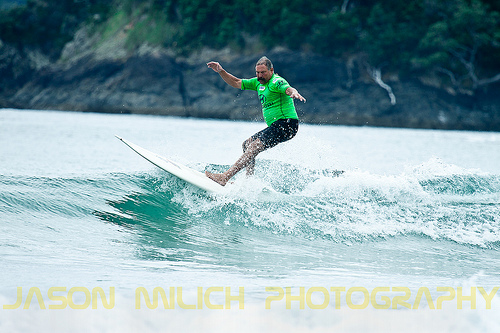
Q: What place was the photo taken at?
A: It was taken at the ocean.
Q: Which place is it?
A: It is an ocean.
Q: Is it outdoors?
A: Yes, it is outdoors.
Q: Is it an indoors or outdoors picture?
A: It is outdoors.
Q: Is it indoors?
A: No, it is outdoors.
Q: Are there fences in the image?
A: No, there are no fences.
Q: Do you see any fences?
A: No, there are no fences.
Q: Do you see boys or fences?
A: No, there are no fences or boys.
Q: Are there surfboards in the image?
A: Yes, there is a surfboard.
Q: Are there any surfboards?
A: Yes, there is a surfboard.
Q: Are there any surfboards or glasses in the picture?
A: Yes, there is a surfboard.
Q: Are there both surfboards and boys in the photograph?
A: No, there is a surfboard but no boys.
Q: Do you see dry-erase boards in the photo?
A: No, there are no dry-erase boards.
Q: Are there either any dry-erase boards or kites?
A: No, there are no dry-erase boards or kites.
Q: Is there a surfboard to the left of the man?
A: Yes, there is a surfboard to the left of the man.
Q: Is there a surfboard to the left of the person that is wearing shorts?
A: Yes, there is a surfboard to the left of the man.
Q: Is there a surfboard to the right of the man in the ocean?
A: No, the surfboard is to the left of the man.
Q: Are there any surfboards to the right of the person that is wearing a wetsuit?
A: No, the surfboard is to the left of the man.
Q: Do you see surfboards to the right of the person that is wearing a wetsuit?
A: No, the surfboard is to the left of the man.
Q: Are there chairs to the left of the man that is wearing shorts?
A: No, there is a surfboard to the left of the man.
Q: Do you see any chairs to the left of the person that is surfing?
A: No, there is a surfboard to the left of the man.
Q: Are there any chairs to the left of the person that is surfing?
A: No, there is a surfboard to the left of the man.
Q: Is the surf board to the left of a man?
A: Yes, the surf board is to the left of a man.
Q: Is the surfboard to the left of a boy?
A: No, the surfboard is to the left of a man.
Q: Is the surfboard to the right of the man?
A: No, the surfboard is to the left of the man.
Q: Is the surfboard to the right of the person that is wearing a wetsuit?
A: No, the surfboard is to the left of the man.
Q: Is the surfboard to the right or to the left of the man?
A: The surfboard is to the left of the man.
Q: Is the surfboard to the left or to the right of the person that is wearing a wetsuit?
A: The surfboard is to the left of the man.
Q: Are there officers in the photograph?
A: No, there are no officers.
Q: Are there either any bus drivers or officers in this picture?
A: No, there are no officers or bus drivers.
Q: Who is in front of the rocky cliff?
A: The man is in front of the cliff.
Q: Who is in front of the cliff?
A: The man is in front of the cliff.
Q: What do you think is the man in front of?
A: The man is in front of the cliff.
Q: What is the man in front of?
A: The man is in front of the cliff.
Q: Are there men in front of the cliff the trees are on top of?
A: Yes, there is a man in front of the cliff.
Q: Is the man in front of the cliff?
A: Yes, the man is in front of the cliff.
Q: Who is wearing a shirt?
A: The man is wearing a shirt.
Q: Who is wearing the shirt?
A: The man is wearing a shirt.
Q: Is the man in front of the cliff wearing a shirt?
A: Yes, the man is wearing a shirt.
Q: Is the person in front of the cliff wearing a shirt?
A: Yes, the man is wearing a shirt.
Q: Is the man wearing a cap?
A: No, the man is wearing a shirt.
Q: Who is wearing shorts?
A: The man is wearing shorts.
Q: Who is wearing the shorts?
A: The man is wearing shorts.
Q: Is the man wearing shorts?
A: Yes, the man is wearing shorts.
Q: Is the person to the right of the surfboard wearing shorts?
A: Yes, the man is wearing shorts.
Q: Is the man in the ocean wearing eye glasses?
A: No, the man is wearing shorts.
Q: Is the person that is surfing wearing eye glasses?
A: No, the man is wearing shorts.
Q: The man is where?
A: The man is in the ocean.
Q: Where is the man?
A: The man is in the ocean.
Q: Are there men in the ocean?
A: Yes, there is a man in the ocean.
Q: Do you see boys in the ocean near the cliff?
A: No, there is a man in the ocean.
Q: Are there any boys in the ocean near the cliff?
A: No, there is a man in the ocean.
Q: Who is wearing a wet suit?
A: The man is wearing a wet suit.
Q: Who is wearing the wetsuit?
A: The man is wearing a wet suit.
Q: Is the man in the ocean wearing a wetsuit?
A: Yes, the man is wearing a wetsuit.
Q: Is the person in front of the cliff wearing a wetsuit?
A: Yes, the man is wearing a wetsuit.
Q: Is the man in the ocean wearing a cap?
A: No, the man is wearing a wetsuit.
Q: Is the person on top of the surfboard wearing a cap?
A: No, the man is wearing a wetsuit.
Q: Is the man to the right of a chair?
A: No, the man is to the right of the surfboard.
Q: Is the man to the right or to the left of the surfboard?
A: The man is to the right of the surfboard.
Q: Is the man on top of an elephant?
A: No, the man is on top of the surf board.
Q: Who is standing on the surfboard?
A: The man is standing on the surfboard.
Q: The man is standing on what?
A: The man is standing on the surfboard.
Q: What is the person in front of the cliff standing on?
A: The man is standing on the surfboard.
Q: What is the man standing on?
A: The man is standing on the surfboard.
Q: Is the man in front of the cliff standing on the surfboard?
A: Yes, the man is standing on the surfboard.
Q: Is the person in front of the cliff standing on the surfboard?
A: Yes, the man is standing on the surfboard.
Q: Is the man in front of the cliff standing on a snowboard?
A: No, the man is standing on the surfboard.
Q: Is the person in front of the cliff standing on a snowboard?
A: No, the man is standing on the surfboard.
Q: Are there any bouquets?
A: No, there are no bouquets.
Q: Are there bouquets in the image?
A: No, there are no bouquets.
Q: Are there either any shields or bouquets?
A: No, there are no bouquets or shields.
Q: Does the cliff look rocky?
A: Yes, the cliff is rocky.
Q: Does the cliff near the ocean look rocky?
A: Yes, the cliff is rocky.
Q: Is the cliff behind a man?
A: Yes, the cliff is behind a man.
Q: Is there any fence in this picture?
A: No, there are no fences.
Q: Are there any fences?
A: No, there are no fences.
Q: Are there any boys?
A: No, there are no boys.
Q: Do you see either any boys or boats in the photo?
A: No, there are no boys or boats.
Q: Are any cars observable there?
A: No, there are no cars.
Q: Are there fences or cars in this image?
A: No, there are no cars or fences.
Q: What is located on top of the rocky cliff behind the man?
A: The trees are on top of the cliff.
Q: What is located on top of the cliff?
A: The trees are on top of the cliff.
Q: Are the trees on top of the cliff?
A: Yes, the trees are on top of the cliff.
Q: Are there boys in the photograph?
A: No, there are no boys.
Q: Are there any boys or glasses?
A: No, there are no boys or glasses.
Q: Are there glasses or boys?
A: No, there are no boys or glasses.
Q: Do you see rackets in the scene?
A: No, there are no rackets.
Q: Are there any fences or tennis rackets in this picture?
A: No, there are no tennis rackets or fences.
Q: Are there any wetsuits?
A: Yes, there is a wetsuit.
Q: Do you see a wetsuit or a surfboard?
A: Yes, there is a wetsuit.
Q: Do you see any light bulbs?
A: No, there are no light bulbs.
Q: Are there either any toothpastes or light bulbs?
A: No, there are no light bulbs or toothpastes.